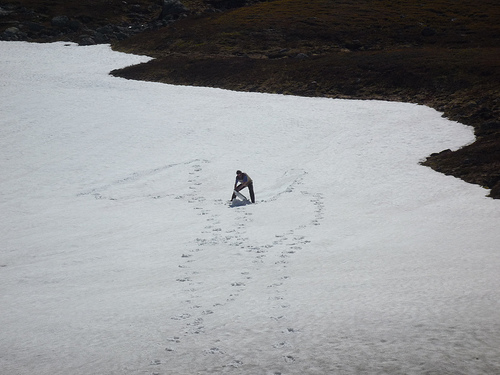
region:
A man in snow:
[226, 159, 271, 214]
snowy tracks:
[131, 149, 216, 224]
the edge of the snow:
[1, 32, 496, 154]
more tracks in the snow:
[185, 211, 313, 368]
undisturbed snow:
[382, 206, 487, 318]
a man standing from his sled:
[216, 168, 271, 220]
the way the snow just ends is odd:
[94, 12, 479, 124]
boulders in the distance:
[25, 3, 205, 63]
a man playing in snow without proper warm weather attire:
[217, 171, 264, 216]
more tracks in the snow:
[268, 174, 338, 351]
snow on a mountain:
[11, 92, 146, 247]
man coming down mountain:
[223, 127, 276, 223]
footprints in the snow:
[171, 219, 326, 355]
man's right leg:
[247, 142, 267, 221]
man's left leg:
[234, 176, 250, 211]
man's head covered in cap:
[235, 167, 245, 183]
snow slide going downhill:
[232, 185, 250, 214]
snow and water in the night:
[411, 92, 494, 183]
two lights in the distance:
[121, 10, 146, 33]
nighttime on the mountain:
[242, 12, 366, 42]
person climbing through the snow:
[217, 163, 273, 214]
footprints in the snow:
[173, 214, 301, 341]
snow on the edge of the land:
[108, 39, 318, 120]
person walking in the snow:
[42, 34, 409, 291]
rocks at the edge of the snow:
[276, 56, 498, 173]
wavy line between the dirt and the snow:
[16, 29, 190, 94]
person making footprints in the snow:
[62, 137, 347, 308]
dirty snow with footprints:
[313, 310, 459, 359]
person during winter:
[216, 160, 278, 216]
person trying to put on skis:
[180, 137, 317, 264]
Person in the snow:
[220, 160, 275, 221]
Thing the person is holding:
[220, 187, 255, 214]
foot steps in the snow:
[54, 147, 373, 373]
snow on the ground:
[2, 38, 497, 373]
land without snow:
[0, 5, 498, 142]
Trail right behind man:
[251, 162, 331, 209]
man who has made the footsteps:
[212, 156, 312, 218]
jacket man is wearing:
[232, 175, 257, 187]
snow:
[6, 53, 478, 370]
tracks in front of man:
[178, 226, 307, 373]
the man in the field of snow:
[190, 127, 342, 351]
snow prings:
[150, 282, 330, 345]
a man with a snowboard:
[230, 166, 263, 205]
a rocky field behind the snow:
[179, 43, 395, 62]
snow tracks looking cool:
[275, 291, 340, 348]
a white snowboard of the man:
[236, 186, 260, 207]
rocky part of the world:
[48, 21, 120, 28]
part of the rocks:
[460, 158, 484, 175]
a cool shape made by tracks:
[215, 162, 325, 373]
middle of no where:
[15, 108, 117, 361]